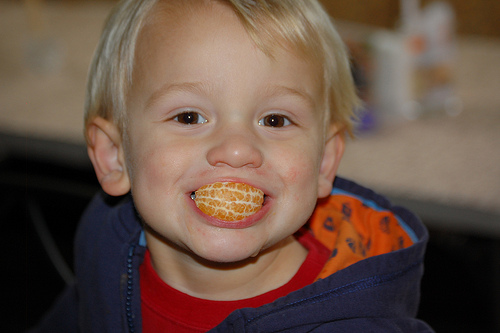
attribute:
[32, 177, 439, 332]
hoodie — purple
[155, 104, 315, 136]
eyes — brown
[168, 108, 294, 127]
eyes — brown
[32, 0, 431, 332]
toddler — blonde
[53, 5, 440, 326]
toddler — happy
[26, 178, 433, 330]
jacket — blue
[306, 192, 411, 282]
inseam — orange, patterned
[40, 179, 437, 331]
sweatshirt — blue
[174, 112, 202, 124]
eye — brown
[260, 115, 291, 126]
eye — brown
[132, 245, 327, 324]
top — red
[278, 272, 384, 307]
stitching — dark blue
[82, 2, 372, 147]
hair — boy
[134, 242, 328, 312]
shirt neck — red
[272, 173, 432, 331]
hood — blue and orange